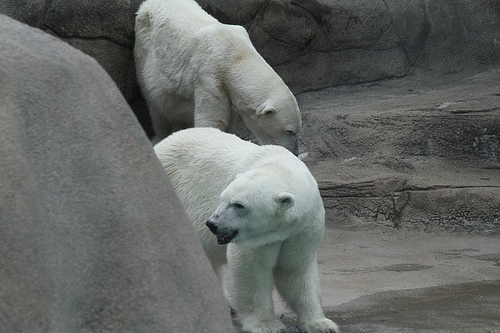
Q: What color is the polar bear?
A: The polar bear is white.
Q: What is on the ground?
A: Water is on the ground.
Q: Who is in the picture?
A: Polar bears are in the picture.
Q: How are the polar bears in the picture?
A: They are on all four legs.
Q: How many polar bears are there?
A: Two polar bears.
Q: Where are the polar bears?
A: They are in a zoo.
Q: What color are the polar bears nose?
A: Thier noses are black.